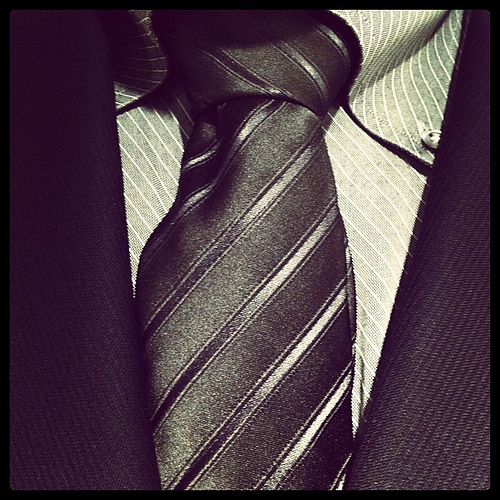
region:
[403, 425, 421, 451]
the suit is black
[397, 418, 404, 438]
the suit is black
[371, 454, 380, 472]
the suit is black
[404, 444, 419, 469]
the suit is black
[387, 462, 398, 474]
the suit is black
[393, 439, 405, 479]
the suit is black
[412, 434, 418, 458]
the suit is black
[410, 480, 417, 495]
the suit is black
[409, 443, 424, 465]
the suit is black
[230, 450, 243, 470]
the tie is black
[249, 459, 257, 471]
the tie is black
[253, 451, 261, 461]
the tie is black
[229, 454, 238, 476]
the tie is black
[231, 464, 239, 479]
the tie is black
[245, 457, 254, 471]
the tie is black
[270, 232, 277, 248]
the tie is black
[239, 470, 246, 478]
the tie is black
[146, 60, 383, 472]
The tie is striped.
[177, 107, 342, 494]
The tie is dark.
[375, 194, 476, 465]
The shirt is pin striped.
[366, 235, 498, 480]
The jacket is dark.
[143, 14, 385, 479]
This is a neck tie.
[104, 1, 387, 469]
The tie is tied to the shirt.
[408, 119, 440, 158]
The button is white.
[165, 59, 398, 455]
The tie is shiny.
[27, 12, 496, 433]
The suit is dark.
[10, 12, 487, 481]
The suite is classic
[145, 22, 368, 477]
The tie is tied.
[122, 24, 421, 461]
The tie is on the shirt.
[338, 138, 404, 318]
The shirt is pin striped.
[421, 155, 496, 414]
The jacket is on the shirt.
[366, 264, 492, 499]
The jacket is black.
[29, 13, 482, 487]
The suit is formal.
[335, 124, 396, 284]
The shirt is grey.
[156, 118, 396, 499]
The stripes are thin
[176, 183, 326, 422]
stripes on the tie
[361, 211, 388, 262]
white shirt behind tie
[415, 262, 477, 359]
jacket next to tie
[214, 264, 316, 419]
thin and thick lines on tie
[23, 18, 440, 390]
a suit with a tie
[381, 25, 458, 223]
button on the shirt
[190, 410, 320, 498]
bottom part of tie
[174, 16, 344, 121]
knot in the tie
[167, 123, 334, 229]
top part of tie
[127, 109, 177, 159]
lines on the tie